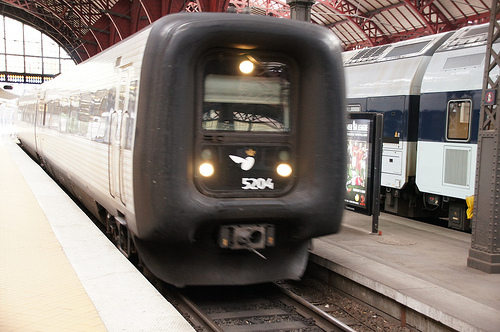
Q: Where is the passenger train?
A: On tracks.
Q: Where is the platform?
A: Next to tracks.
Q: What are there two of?
A: Passenger trains in station.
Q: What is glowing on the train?
A: Three white lights.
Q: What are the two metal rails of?
A: Tracks.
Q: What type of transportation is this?
A: A train.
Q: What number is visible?
A: 5204.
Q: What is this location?
A: Train station.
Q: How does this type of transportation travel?
A: On tracks.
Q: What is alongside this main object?
A: Another train.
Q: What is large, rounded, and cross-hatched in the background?
A: Window.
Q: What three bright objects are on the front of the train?
A: Lights.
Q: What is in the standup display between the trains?
A: Advertisement.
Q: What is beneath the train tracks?
A: Gravel.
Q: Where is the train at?
A: The station.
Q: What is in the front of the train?
A: A black border.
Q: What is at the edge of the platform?
A: A white border.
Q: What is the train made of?
A: Metal.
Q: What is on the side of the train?
A: Doors.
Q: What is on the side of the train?
A: Windows.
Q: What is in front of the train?
A: Headlights.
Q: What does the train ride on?
A: Tracks.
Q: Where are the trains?
A: On a platform.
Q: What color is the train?
A: Silver.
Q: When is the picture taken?
A: During the day.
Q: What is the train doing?
A: Leaving the station.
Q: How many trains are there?
A: Two.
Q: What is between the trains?
A: Columns.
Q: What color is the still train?
A: White and Blue.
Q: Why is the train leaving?
A: It's full.